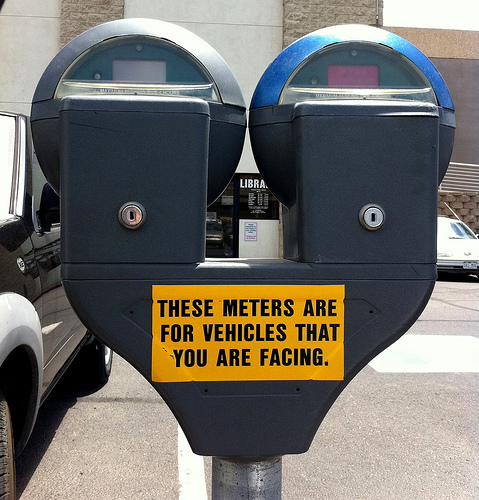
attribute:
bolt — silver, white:
[356, 201, 388, 233]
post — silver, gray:
[210, 456, 283, 500]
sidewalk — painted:
[13, 274, 477, 497]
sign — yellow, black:
[152, 284, 345, 382]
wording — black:
[158, 301, 340, 367]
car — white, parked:
[436, 214, 478, 277]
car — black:
[1, 108, 113, 500]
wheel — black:
[71, 335, 113, 399]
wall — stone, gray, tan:
[281, 1, 384, 54]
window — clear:
[208, 173, 236, 259]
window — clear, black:
[238, 176, 280, 220]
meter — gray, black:
[29, 17, 247, 262]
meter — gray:
[250, 23, 457, 261]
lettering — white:
[241, 177, 268, 214]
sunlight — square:
[195, 257, 250, 269]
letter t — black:
[157, 298, 167, 320]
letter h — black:
[167, 297, 181, 319]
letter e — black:
[181, 299, 193, 318]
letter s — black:
[191, 297, 203, 318]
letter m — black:
[223, 299, 237, 321]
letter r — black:
[270, 297, 284, 315]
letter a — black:
[302, 299, 314, 318]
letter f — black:
[159, 323, 171, 344]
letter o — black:
[171, 323, 183, 344]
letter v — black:
[201, 321, 215, 343]